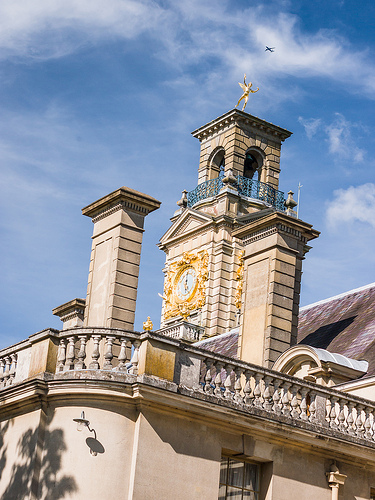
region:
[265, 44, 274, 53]
airplane flying in sky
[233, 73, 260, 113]
statue of angel on top of building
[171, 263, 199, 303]
clock on tower of building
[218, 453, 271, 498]
window in wall of building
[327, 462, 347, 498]
waterspout in wall of building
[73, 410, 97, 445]
light hanging from wall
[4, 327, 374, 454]
stone balcony on ornate building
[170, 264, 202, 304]
white round clock face in building tower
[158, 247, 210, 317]
ornate gold frame surrounding white clock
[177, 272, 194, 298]
black numbers on white clock face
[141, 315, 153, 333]
ornate gold ball on balcony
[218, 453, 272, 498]
window in side of building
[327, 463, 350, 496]
drain pipes on side of building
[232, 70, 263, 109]
gold Greek mythical statue decorating top of building's tower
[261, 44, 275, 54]
plane flying in blue sky above building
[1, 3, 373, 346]
sunny bright blue sky with white clouds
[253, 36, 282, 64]
The plane in the sky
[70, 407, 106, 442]
The light on the building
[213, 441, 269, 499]
The window on the bulding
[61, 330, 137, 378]
The balcony poles are dirty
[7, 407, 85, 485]
The tree shadows on the building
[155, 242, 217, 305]
The clock is surrounded by gold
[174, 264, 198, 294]
The clock has a white face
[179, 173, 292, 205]
The balcony around the top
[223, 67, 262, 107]
The gold statue on top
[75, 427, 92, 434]
the bulb is clear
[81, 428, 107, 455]
shadow on the wall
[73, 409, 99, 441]
light on the wall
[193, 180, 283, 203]
the railing is blue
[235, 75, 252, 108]
figure on the tower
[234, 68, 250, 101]
the figure is golden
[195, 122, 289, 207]
railing around the tower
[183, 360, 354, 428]
the balcony is stone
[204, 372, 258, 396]
columns in the balcony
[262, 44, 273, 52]
Airplane flying in the air over building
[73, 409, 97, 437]
Light on side of building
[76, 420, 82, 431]
Clear lightbulb in light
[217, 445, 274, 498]
Window on side of building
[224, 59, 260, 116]
a statue on top of tower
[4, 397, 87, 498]
shadow on the building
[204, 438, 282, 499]
window on the building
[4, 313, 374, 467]
railing on the building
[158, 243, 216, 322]
clock on the tower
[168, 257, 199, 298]
face of the clock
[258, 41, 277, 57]
plane in the sky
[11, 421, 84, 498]
the shadow of a tree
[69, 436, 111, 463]
the shadow of a lamp